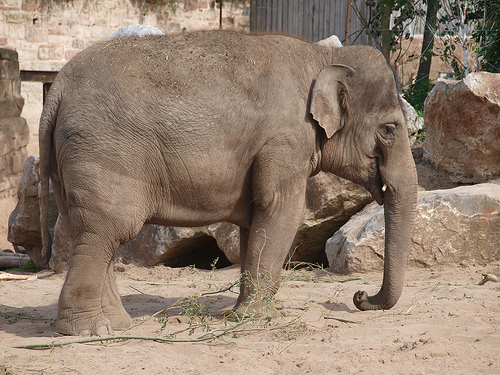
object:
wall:
[0, 0, 484, 173]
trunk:
[351, 159, 419, 311]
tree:
[357, 3, 499, 113]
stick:
[0, 253, 336, 354]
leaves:
[178, 295, 237, 342]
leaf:
[358, 7, 416, 50]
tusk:
[377, 178, 389, 194]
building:
[0, 0, 263, 259]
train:
[38, 26, 431, 338]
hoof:
[231, 299, 277, 327]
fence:
[247, 0, 390, 68]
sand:
[0, 248, 493, 373]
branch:
[13, 227, 331, 354]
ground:
[0, 258, 500, 373]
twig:
[15, 240, 328, 356]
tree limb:
[13, 328, 179, 353]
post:
[18, 68, 55, 104]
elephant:
[369, 30, 416, 335]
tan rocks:
[421, 64, 498, 271]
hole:
[159, 231, 231, 269]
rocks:
[116, 154, 373, 266]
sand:
[0, 293, 499, 374]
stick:
[381, 181, 389, 192]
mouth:
[363, 150, 391, 204]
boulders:
[324, 59, 499, 280]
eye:
[376, 121, 401, 135]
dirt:
[0, 263, 495, 373]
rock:
[419, 69, 499, 179]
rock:
[324, 180, 484, 270]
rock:
[308, 31, 424, 153]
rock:
[206, 166, 373, 266]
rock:
[0, 45, 30, 197]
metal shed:
[243, 14, 442, 191]